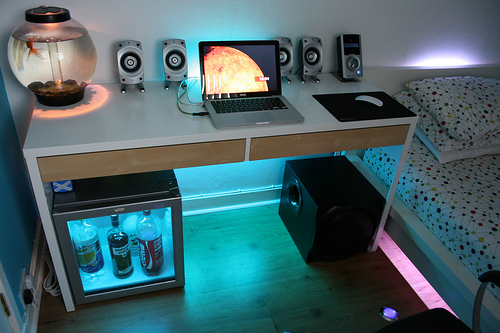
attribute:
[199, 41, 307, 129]
computer — silver, small, open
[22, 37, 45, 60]
goldfish — swimming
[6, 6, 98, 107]
aquarium — round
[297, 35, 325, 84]
speaker — silver, black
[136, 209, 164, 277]
bottle — emtpy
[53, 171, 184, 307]
fridge — square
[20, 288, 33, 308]
outlet — black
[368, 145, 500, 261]
sheet — yellow, dotted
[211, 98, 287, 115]
keyboard — black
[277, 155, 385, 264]
sub woofer — black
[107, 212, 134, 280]
bottle — glass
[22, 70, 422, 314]
desk — white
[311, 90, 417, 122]
mousepad — black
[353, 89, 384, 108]
mouse — white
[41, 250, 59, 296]
cord — white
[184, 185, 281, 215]
baseboard — white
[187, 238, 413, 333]
floor — wooden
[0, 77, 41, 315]
wall — blue